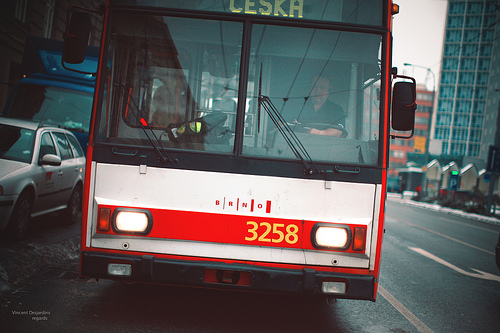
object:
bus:
[61, 0, 416, 304]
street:
[1, 194, 497, 332]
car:
[0, 118, 87, 242]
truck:
[0, 36, 114, 159]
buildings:
[0, 0, 100, 42]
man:
[275, 74, 349, 138]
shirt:
[278, 99, 345, 137]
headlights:
[315, 225, 348, 247]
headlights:
[115, 211, 150, 233]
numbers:
[245, 221, 299, 244]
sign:
[229, 0, 305, 18]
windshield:
[95, 9, 385, 170]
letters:
[215, 200, 219, 206]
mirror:
[62, 12, 91, 64]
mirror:
[391, 82, 417, 131]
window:
[457, 86, 471, 101]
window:
[463, 41, 480, 56]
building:
[430, 0, 498, 158]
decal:
[44, 171, 52, 181]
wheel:
[290, 122, 348, 138]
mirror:
[203, 51, 237, 78]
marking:
[407, 246, 500, 283]